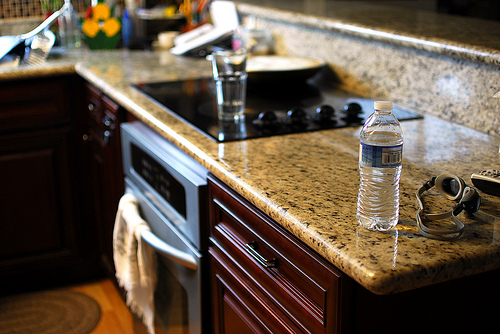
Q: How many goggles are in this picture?
A: One.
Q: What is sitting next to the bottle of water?
A: Goggles.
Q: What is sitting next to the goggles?
A: A bottle of water.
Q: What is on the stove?
A: A glass.